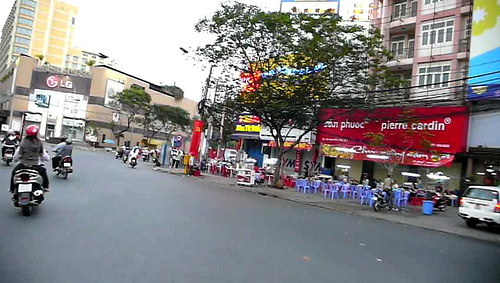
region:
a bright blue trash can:
[422, 199, 433, 214]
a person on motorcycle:
[10, 125, 50, 214]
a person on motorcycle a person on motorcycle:
[0, 127, 20, 164]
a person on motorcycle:
[127, 144, 139, 168]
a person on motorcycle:
[115, 141, 125, 158]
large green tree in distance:
[180, 2, 408, 185]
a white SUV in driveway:
[458, 183, 498, 231]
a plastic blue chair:
[295, 177, 302, 189]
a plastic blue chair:
[303, 179, 308, 192]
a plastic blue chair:
[308, 179, 318, 194]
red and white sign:
[297, 103, 444, 171]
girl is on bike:
[0, 104, 70, 228]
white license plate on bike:
[11, 181, 63, 211]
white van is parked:
[438, 190, 498, 222]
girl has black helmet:
[15, 122, 60, 155]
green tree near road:
[172, 0, 379, 200]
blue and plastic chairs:
[281, 178, 396, 209]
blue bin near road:
[401, 183, 436, 220]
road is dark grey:
[181, 238, 326, 282]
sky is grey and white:
[98, 0, 203, 102]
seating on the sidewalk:
[286, 165, 408, 208]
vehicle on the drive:
[448, 184, 498, 231]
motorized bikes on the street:
[4, 127, 159, 227]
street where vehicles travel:
[65, 191, 241, 273]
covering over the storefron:
[319, 103, 466, 143]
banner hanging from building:
[321, 145, 456, 164]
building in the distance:
[3, 6, 108, 70]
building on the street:
[86, 58, 196, 148]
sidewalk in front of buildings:
[278, 180, 436, 202]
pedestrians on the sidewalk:
[172, 150, 192, 172]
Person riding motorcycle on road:
[10, 124, 51, 215]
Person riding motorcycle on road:
[51, 137, 74, 180]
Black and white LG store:
[20, 63, 92, 144]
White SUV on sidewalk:
[457, 185, 499, 232]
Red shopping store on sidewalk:
[317, 103, 468, 206]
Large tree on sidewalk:
[177, 0, 412, 193]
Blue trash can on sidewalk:
[419, 197, 434, 215]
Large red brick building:
[365, 0, 470, 106]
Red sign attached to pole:
[189, 119, 203, 161]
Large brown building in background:
[85, 63, 209, 150]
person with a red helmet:
[8, 124, 49, 194]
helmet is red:
[24, 124, 39, 137]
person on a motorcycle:
[8, 124, 49, 194]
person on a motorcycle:
[0, 128, 17, 158]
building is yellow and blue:
[0, 0, 78, 75]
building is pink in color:
[367, 0, 472, 107]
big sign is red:
[315, 105, 470, 168]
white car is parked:
[457, 184, 499, 231]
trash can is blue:
[421, 199, 435, 214]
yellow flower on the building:
[470, 0, 499, 34]